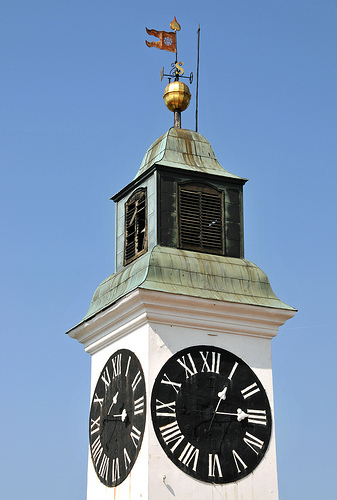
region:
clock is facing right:
[149, 344, 273, 486]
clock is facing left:
[87, 348, 145, 488]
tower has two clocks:
[65, 15, 298, 499]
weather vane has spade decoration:
[168, 15, 181, 31]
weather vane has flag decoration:
[142, 25, 176, 51]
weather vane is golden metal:
[145, 14, 193, 128]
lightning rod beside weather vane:
[194, 21, 201, 131]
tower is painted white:
[69, 289, 296, 498]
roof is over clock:
[65, 246, 295, 334]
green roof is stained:
[66, 243, 297, 333]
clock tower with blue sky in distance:
[53, 7, 303, 498]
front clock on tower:
[150, 335, 275, 486]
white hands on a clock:
[213, 384, 250, 426]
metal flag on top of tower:
[136, 14, 186, 55]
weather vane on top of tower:
[143, 51, 204, 121]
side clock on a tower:
[82, 349, 153, 488]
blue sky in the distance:
[10, 207, 66, 435]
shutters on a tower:
[169, 174, 233, 256]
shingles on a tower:
[143, 251, 295, 312]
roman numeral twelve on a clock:
[198, 347, 223, 379]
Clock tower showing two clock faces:
[78, 346, 277, 488]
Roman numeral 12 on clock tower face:
[197, 347, 222, 375]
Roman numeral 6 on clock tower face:
[205, 451, 223, 478]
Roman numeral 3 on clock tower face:
[244, 406, 269, 426]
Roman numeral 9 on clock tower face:
[153, 398, 179, 418]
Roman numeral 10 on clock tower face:
[158, 370, 182, 394]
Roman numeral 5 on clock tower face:
[228, 446, 249, 472]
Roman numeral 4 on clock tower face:
[240, 428, 266, 454]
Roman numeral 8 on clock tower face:
[156, 418, 184, 454]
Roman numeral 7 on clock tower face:
[178, 440, 200, 473]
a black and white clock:
[54, 319, 284, 497]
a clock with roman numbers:
[155, 351, 270, 478]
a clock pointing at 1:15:
[161, 347, 264, 466]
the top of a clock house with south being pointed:
[137, 13, 233, 124]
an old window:
[160, 179, 250, 259]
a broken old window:
[104, 173, 160, 280]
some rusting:
[124, 134, 240, 171]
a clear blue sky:
[272, 3, 330, 280]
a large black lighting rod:
[193, 17, 212, 135]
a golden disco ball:
[155, 78, 192, 116]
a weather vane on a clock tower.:
[137, 18, 203, 83]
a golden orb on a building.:
[154, 73, 198, 128]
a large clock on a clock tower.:
[150, 343, 272, 485]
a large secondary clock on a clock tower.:
[86, 345, 148, 486]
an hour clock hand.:
[205, 384, 230, 423]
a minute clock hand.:
[215, 403, 247, 421]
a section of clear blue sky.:
[226, 51, 299, 90]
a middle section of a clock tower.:
[108, 130, 249, 204]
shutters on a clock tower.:
[112, 186, 149, 270]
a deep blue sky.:
[74, 50, 117, 121]